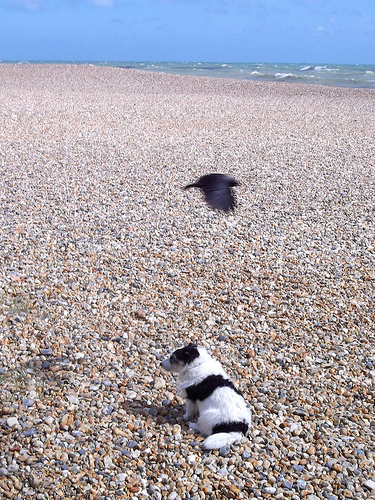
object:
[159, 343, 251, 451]
dog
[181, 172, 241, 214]
bird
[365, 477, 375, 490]
rocks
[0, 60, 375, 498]
beach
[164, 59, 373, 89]
ocean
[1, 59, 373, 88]
distance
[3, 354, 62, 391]
shadow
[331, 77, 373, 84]
waves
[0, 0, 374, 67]
sky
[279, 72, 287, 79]
white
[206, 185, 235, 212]
wing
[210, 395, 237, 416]
white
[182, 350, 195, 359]
black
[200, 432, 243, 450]
tail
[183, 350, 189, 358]
ears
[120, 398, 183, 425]
shadow